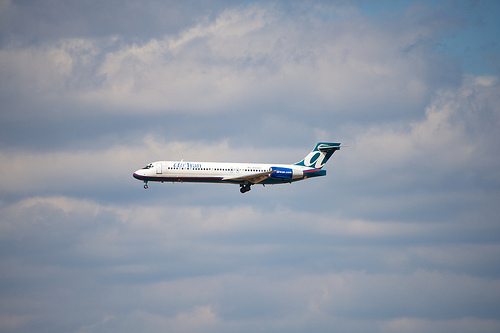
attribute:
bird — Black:
[58, 262, 80, 276]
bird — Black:
[410, 302, 445, 314]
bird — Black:
[384, 279, 441, 288]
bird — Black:
[396, 315, 468, 321]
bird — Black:
[361, 307, 427, 312]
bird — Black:
[388, 306, 438, 319]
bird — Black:
[370, 311, 433, 321]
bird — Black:
[439, 275, 469, 287]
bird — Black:
[383, 296, 426, 304]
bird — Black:
[343, 278, 413, 288]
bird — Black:
[326, 306, 406, 322]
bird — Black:
[349, 313, 408, 319]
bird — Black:
[415, 303, 473, 311]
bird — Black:
[395, 298, 445, 311]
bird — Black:
[377, 304, 412, 310]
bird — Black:
[366, 316, 420, 323]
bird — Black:
[385, 318, 430, 323]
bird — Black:
[338, 302, 392, 306]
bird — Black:
[327, 288, 401, 300]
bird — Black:
[367, 308, 427, 321]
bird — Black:
[336, 288, 387, 301]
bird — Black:
[361, 316, 440, 329]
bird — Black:
[323, 269, 401, 319]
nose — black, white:
[128, 165, 148, 183]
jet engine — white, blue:
[126, 134, 347, 199]